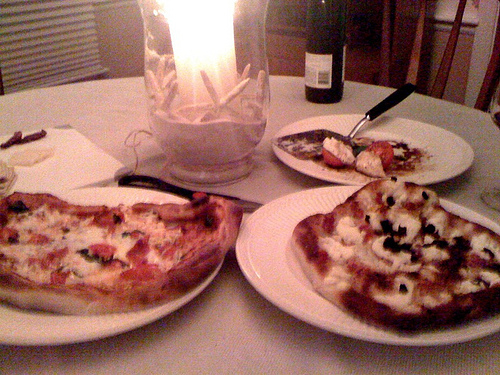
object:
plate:
[0, 127, 131, 196]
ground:
[363, 130, 405, 178]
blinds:
[0, 1, 139, 107]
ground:
[436, 160, 475, 190]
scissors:
[116, 172, 263, 213]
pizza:
[2, 193, 236, 310]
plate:
[234, 185, 498, 347]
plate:
[2, 186, 213, 346]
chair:
[371, 1, 499, 112]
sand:
[149, 98, 269, 178]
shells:
[321, 136, 357, 164]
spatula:
[272, 82, 417, 160]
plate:
[265, 111, 476, 189]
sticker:
[304, 51, 332, 89]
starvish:
[109, 0, 278, 167]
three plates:
[5, 109, 498, 356]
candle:
[165, 0, 236, 122]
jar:
[136, 2, 268, 184]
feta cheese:
[395, 217, 422, 240]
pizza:
[289, 177, 499, 337]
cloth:
[1, 71, 499, 373]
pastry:
[324, 125, 398, 176]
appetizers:
[1, 128, 45, 153]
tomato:
[366, 143, 393, 166]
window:
[8, 5, 98, 85]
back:
[342, 5, 496, 95]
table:
[4, 65, 497, 370]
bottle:
[302, 2, 346, 104]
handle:
[362, 83, 417, 122]